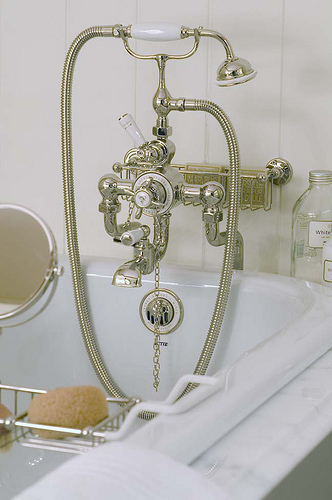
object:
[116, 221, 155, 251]
tap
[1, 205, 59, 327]
mirror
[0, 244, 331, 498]
tub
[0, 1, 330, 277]
wall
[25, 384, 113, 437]
sponge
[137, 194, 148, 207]
symbol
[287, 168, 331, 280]
bottle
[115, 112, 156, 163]
handle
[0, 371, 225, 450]
rack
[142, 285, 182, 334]
drain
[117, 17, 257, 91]
spigot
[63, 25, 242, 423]
hose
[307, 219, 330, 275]
label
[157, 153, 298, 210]
tray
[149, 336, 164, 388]
chain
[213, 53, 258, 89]
head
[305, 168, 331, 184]
cap